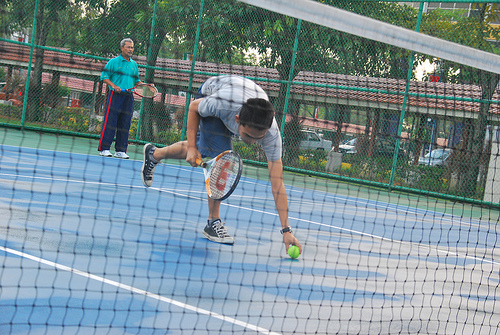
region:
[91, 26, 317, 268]
two men playing tennis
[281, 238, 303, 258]
fingers wrapped around the tennis ball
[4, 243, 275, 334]
white line painted on the court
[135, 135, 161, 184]
back leg in the air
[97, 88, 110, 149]
red stripe down the side of the leg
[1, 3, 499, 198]
tall chain link fence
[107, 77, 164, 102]
tennis racket in front of the body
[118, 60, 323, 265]
man is bending over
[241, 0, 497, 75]
white strip at the top of the net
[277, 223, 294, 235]
watch around the wrist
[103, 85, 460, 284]
the man is playing tennis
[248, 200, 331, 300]
the man is reaching for the ball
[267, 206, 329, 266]
the man is wearing a watch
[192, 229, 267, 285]
a black tennis net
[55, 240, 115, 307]
white lines are on the ground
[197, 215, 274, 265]
the man is wearing tennis shoe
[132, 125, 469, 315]
the man is holding a tennis racquet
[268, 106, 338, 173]
a white car is parked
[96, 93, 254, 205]
the man is wearing blue and red pants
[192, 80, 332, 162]
the man is wearing a gray shirt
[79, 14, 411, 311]
men on a tennis court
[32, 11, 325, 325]
two men on a tennis court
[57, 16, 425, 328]
men standing on a tennis court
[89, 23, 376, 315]
men playing tennis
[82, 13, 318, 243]
men holding a tennis racket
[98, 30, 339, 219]
men holding a racket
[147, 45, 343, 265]
a man leaning forward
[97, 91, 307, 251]
a man leaning down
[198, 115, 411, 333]
a man grabing a ball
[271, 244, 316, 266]
tennis ball on a court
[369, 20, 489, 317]
net of a tennis court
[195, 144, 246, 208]
racket in man's hand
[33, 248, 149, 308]
white painted line on court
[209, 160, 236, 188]
w on a racket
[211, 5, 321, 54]
green leaves on a tree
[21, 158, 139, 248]
blue ground of a tennis court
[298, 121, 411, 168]
cars on the street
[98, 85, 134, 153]
pants on a man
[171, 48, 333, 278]
boy is picking up the ball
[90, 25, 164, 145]
the man is holding a racket